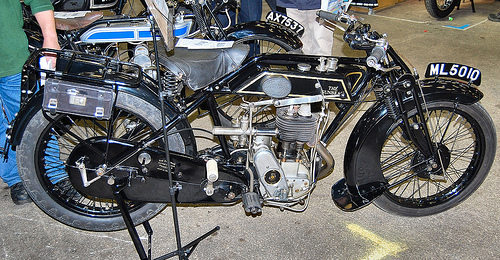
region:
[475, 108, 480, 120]
part of a wheel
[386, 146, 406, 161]
part of a spoke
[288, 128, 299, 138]
part of an engine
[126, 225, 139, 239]
edge of a stand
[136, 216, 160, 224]
part of a stand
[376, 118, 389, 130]
part of a wheel cap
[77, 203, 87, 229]
back of a wheel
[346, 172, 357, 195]
part of a wheel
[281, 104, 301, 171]
part of an engine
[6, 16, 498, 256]
Old fashioned motorcyle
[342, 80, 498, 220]
front tire of old motorcycle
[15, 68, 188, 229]
back tire of old motorcycle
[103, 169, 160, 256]
kickstand of old motorcycle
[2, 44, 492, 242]
motorcycle is black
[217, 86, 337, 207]
engine in old motorcycle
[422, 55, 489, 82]
license plate on old motorcycle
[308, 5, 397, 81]
handlebars on old motorcycle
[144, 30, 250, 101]
seat on old motorcycle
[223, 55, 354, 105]
gas tank on old motorcycle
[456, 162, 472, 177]
part of a spoke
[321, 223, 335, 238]
part of a parking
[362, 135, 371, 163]
part of a wheel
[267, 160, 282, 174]
part of an engine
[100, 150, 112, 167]
back of a wheel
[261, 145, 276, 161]
part of an engine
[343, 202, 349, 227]
part of a wheel cap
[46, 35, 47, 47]
part of an arm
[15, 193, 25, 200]
part of a boot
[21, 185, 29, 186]
edge of a boot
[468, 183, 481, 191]
part of a wheel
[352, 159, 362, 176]
part of a post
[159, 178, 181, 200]
edge of a wheel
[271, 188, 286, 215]
part of an engine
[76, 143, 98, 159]
part of a wheel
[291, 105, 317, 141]
edge of an engine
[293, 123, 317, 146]
edge of a rail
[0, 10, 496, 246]
The motorcycle is on display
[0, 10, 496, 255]
The motorcycle is for sale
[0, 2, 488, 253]
The motorcycle is parked on concrete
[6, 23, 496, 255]
The motorcycle is an antique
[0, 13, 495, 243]
The motorcycle belongs to a collector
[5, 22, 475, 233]
The motorcycle has a motor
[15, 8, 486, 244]
The motorcycle is ready to ride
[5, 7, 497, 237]
A motorcycle is at a show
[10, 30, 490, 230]
The motorcycle is part of a collection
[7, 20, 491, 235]
The motorcycle is in a museum